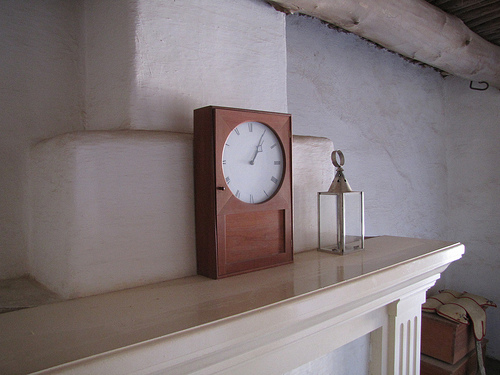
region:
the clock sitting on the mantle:
[190, 96, 297, 265]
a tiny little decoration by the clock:
[308, 143, 369, 252]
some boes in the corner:
[411, 285, 487, 373]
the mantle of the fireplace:
[0, 233, 470, 374]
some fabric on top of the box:
[431, 293, 492, 336]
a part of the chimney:
[31, 3, 351, 280]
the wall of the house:
[301, 19, 467, 244]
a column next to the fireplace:
[381, 311, 423, 373]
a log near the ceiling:
[358, 8, 498, 107]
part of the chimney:
[28, 5, 358, 262]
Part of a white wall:
[28, 120, 70, 206]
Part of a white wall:
[35, 246, 167, 362]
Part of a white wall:
[130, 166, 165, 229]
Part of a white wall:
[106, 99, 158, 150]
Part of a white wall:
[120, 15, 177, 58]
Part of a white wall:
[197, 14, 246, 66]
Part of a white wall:
[10, 28, 115, 88]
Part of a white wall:
[318, 70, 377, 136]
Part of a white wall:
[385, 134, 480, 231]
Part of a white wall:
[403, 75, 453, 120]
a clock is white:
[188, 92, 309, 283]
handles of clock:
[244, 126, 275, 170]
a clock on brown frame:
[182, 82, 307, 290]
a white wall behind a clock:
[11, 0, 491, 291]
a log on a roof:
[295, 0, 497, 91]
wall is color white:
[321, 45, 491, 222]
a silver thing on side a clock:
[221, 105, 378, 275]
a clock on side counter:
[0, 71, 470, 359]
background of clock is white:
[214, 113, 292, 208]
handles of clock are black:
[218, 112, 289, 207]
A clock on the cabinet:
[220, 116, 280, 206]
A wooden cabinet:
[195, 211, 308, 266]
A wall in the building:
[112, 95, 182, 265]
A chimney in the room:
[125, 267, 352, 349]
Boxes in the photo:
[430, 312, 470, 373]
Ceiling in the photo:
[379, 10, 489, 66]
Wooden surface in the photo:
[270, 257, 389, 338]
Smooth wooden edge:
[82, 289, 193, 333]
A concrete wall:
[397, 107, 457, 219]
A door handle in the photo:
[218, 184, 235, 200]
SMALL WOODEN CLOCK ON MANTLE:
[181, 100, 315, 291]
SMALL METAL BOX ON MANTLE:
[317, 141, 377, 256]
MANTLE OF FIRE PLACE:
[34, 235, 470, 372]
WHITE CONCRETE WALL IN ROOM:
[67, 21, 451, 232]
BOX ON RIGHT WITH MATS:
[404, 280, 486, 361]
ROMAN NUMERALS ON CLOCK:
[234, 142, 295, 217]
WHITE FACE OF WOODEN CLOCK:
[204, 128, 295, 212]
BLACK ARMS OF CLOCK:
[220, 112, 290, 168]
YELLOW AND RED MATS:
[450, 285, 499, 340]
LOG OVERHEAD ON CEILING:
[369, 15, 485, 87]